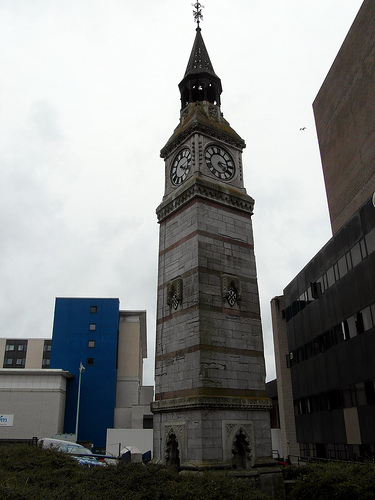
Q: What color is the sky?
A: Gray.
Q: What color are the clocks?
A: White and black.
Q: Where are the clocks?
A: On the tower.